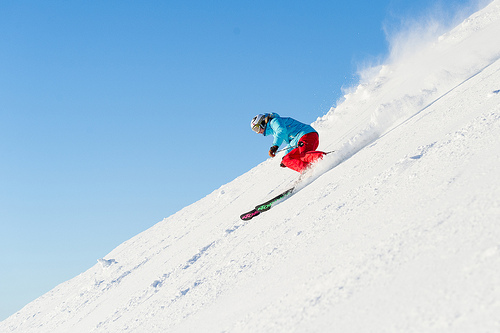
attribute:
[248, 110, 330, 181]
woman — skiing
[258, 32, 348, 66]
sky — blue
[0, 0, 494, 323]
sky — clear, blue, very clear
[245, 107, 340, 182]
person — wearing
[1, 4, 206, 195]
sky — blue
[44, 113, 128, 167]
sky — blue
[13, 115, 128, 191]
clouds — white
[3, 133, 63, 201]
clouds — white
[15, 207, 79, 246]
clouds — white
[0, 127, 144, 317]
cloud — white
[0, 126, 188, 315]
cloud — white